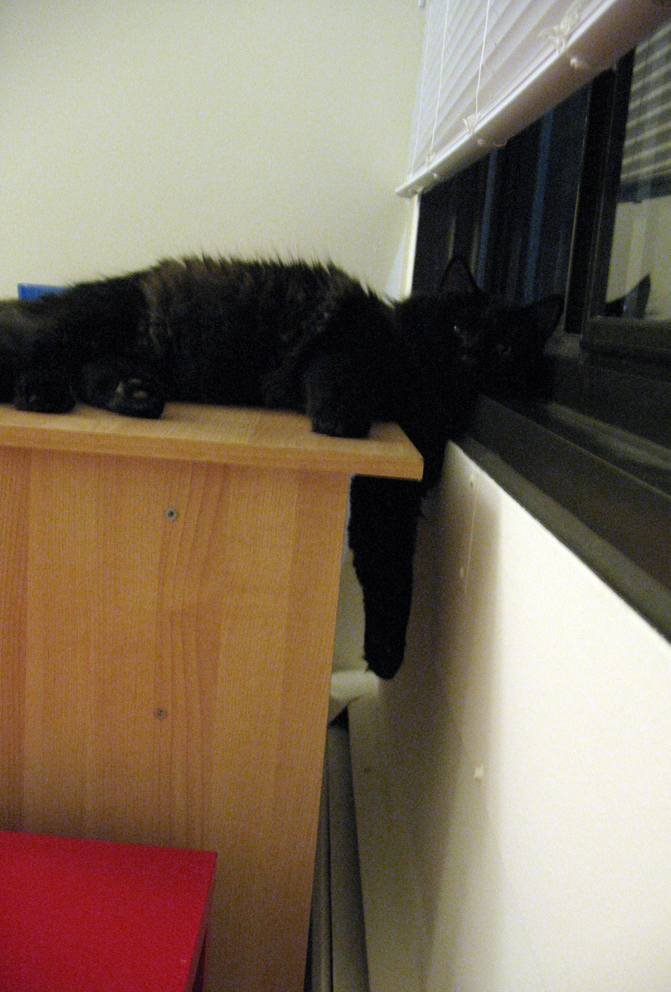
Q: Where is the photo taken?
A: A room.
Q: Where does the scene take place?
A: On a counter.